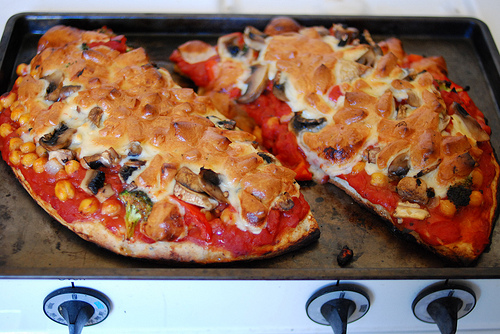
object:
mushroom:
[141, 200, 190, 241]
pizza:
[1, 19, 325, 268]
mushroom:
[78, 159, 107, 196]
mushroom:
[38, 121, 78, 151]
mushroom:
[198, 166, 233, 206]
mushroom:
[40, 73, 68, 103]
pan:
[0, 9, 499, 283]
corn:
[77, 196, 99, 217]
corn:
[54, 179, 75, 203]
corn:
[64, 160, 80, 176]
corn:
[32, 158, 49, 174]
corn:
[0, 120, 16, 139]